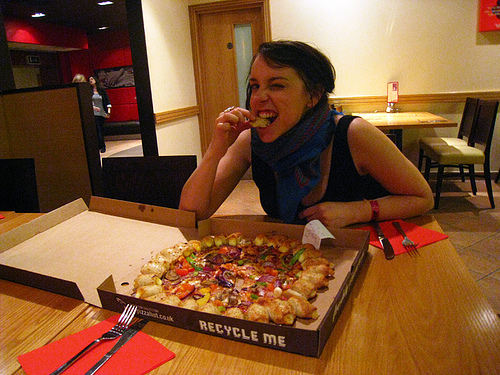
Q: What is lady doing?
A: Eating pizza.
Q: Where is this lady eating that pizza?
A: Inside a restaurant.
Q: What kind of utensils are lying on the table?
A: A fork and a knife.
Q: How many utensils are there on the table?
A: Two.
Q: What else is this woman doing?
A: Winking.